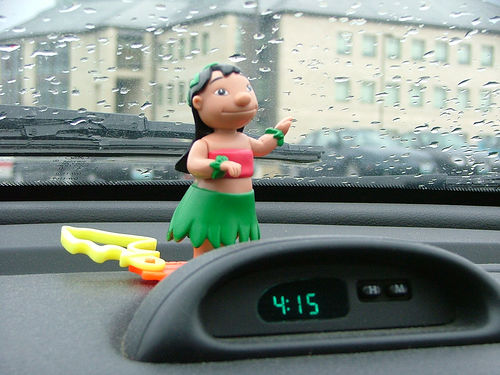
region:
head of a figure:
[197, 53, 263, 125]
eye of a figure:
[214, 80, 229, 93]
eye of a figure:
[238, 80, 258, 95]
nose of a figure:
[233, 94, 263, 105]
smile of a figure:
[223, 105, 273, 124]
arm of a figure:
[246, 103, 302, 167]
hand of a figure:
[274, 116, 299, 131]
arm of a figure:
[193, 157, 221, 177]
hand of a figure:
[223, 159, 246, 180]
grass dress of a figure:
[165, 183, 275, 253]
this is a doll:
[145, 46, 330, 253]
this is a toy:
[45, 210, 225, 302]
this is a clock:
[236, 274, 350, 334]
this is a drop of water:
[107, 82, 143, 99]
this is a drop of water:
[307, 95, 347, 130]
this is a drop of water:
[332, 65, 360, 97]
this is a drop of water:
[225, 52, 255, 68]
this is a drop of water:
[252, 23, 272, 48]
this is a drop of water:
[25, 49, 64, 69]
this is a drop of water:
[131, 85, 159, 116]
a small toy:
[151, 45, 301, 257]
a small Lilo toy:
[166, 47, 329, 246]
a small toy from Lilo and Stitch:
[152, 17, 317, 259]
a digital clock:
[250, 277, 353, 332]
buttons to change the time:
[352, 266, 434, 308]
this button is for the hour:
[347, 275, 384, 305]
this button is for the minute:
[388, 275, 411, 302]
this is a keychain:
[51, 197, 173, 288]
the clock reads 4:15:
[247, 275, 352, 323]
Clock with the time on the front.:
[263, 290, 277, 297]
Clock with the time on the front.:
[310, 242, 312, 323]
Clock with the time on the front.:
[359, 233, 386, 321]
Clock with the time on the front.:
[202, 216, 203, 281]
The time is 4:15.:
[272, 289, 320, 317]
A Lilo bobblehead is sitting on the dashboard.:
[166, 60, 291, 257]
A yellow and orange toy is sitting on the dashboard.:
[59, 221, 191, 286]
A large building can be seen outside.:
[1, 0, 499, 149]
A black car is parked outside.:
[287, 127, 432, 177]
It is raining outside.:
[1, 0, 498, 187]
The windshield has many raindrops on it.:
[1, 0, 498, 188]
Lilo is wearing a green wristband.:
[210, 155, 226, 178]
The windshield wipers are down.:
[0, 106, 327, 162]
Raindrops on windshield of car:
[3, 2, 497, 189]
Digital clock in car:
[259, 285, 341, 320]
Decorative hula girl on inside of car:
[58, 60, 295, 281]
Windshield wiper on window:
[1, 105, 322, 162]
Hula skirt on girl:
[167, 184, 258, 244]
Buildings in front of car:
[2, 4, 498, 154]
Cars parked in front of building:
[5, 118, 498, 183]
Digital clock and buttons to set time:
[249, 277, 413, 320]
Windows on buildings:
[6, 39, 493, 109]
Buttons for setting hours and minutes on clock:
[359, 277, 409, 297]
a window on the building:
[339, 76, 346, 91]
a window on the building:
[357, 78, 367, 101]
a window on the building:
[385, 83, 407, 111]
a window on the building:
[435, 88, 450, 107]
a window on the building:
[454, 90, 468, 105]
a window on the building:
[332, 30, 352, 47]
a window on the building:
[360, 33, 372, 54]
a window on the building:
[386, 35, 398, 57]